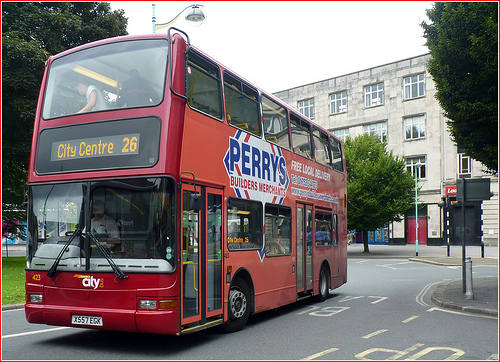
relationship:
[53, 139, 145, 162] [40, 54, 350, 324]
sign on bus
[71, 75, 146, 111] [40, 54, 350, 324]
people on bus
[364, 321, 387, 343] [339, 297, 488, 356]
lines on road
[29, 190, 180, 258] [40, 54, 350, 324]
windshield wipes bus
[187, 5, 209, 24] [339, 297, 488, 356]
light in road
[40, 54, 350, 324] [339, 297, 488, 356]
bus on road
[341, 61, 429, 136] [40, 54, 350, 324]
building behind bus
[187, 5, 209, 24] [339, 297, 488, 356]
light on road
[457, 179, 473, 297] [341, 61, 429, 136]
pole near building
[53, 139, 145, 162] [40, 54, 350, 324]
sign of bus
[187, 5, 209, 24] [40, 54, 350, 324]
light near bus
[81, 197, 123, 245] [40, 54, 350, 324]
driver of bus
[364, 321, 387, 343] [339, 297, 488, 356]
lines in road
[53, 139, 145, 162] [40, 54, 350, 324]
sign front of bus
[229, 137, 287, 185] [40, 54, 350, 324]
letters on bus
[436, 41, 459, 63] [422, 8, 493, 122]
leaves on tree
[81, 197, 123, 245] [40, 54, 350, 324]
driver on bus